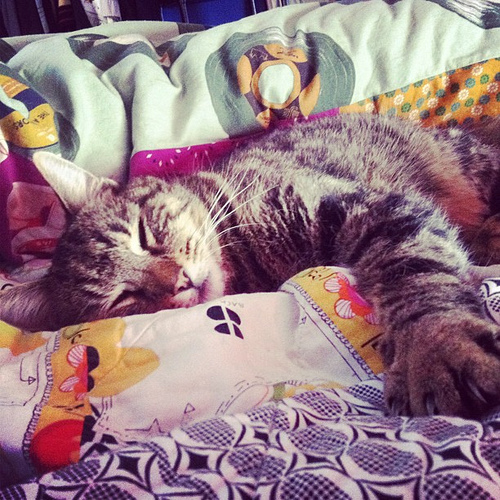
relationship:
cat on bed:
[24, 109, 496, 419] [1, 0, 498, 498]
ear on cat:
[120, 155, 188, 202] [81, 117, 498, 414]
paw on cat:
[378, 300, 498, 397] [24, 109, 496, 419]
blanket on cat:
[13, 309, 416, 499] [24, 109, 496, 419]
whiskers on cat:
[199, 169, 278, 253] [24, 109, 496, 419]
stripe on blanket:
[337, 57, 499, 141] [3, 0, 499, 500]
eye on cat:
[131, 206, 156, 255] [24, 109, 496, 419]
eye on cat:
[106, 279, 141, 309] [24, 109, 496, 419]